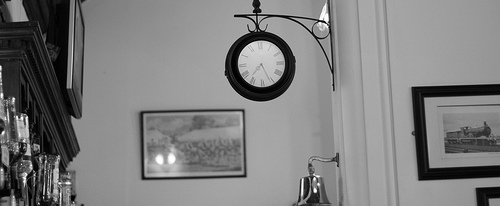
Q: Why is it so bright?
A: Lights are on.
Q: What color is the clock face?
A: White.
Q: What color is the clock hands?
A: Black.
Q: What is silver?
A: The lamp.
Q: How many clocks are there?
A: One.